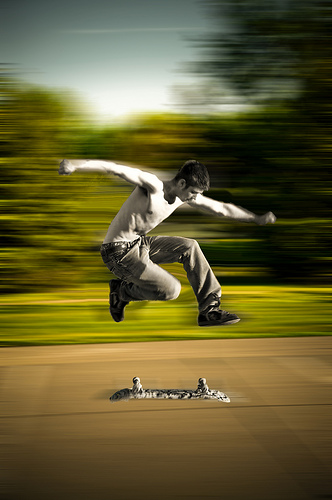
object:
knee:
[156, 277, 182, 300]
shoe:
[109, 278, 129, 323]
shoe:
[198, 304, 241, 326]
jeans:
[100, 233, 221, 314]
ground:
[244, 365, 304, 460]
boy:
[58, 158, 277, 327]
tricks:
[42, 137, 278, 391]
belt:
[100, 242, 129, 256]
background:
[0, 0, 332, 500]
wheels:
[198, 377, 208, 386]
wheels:
[132, 376, 140, 384]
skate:
[108, 376, 231, 405]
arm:
[58, 158, 149, 191]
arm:
[191, 193, 277, 225]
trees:
[162, 0, 332, 292]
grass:
[0, 281, 330, 348]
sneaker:
[197, 305, 241, 328]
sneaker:
[106, 277, 132, 322]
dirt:
[0, 342, 332, 500]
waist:
[101, 225, 143, 248]